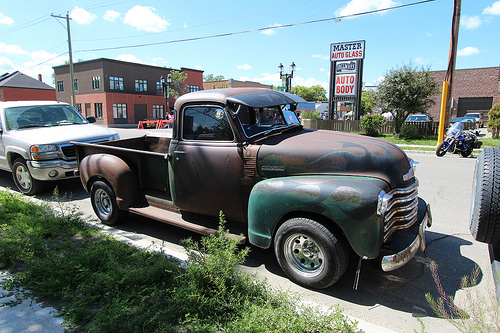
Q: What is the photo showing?
A: It is showing a road.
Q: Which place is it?
A: It is a road.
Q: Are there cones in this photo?
A: No, there are no cones.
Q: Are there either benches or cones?
A: No, there are no cones or benches.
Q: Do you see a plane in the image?
A: No, there are no airplanes.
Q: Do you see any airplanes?
A: No, there are no airplanes.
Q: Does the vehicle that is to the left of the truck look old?
A: Yes, the vehicle is old.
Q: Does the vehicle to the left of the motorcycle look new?
A: No, the vehicle is old.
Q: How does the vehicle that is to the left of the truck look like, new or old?
A: The vehicle is old.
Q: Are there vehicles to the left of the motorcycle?
A: Yes, there is a vehicle to the left of the motorcycle.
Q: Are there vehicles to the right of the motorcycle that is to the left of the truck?
A: No, the vehicle is to the left of the motorcycle.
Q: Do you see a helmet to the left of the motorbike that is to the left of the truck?
A: No, there is a vehicle to the left of the motorcycle.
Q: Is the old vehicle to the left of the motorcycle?
A: Yes, the vehicle is to the left of the motorcycle.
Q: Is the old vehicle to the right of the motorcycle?
A: No, the vehicle is to the left of the motorcycle.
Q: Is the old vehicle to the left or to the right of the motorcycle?
A: The vehicle is to the left of the motorcycle.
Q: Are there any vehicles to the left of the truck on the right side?
A: Yes, there is a vehicle to the left of the truck.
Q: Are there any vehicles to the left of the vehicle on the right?
A: Yes, there is a vehicle to the left of the truck.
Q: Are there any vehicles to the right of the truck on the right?
A: No, the vehicle is to the left of the truck.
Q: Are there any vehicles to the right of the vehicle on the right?
A: No, the vehicle is to the left of the truck.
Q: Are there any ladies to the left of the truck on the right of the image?
A: No, there is a vehicle to the left of the truck.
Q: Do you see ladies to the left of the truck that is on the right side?
A: No, there is a vehicle to the left of the truck.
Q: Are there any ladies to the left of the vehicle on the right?
A: No, there is a vehicle to the left of the truck.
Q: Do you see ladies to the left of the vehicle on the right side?
A: No, there is a vehicle to the left of the truck.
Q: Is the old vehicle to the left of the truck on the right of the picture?
A: Yes, the vehicle is to the left of the truck.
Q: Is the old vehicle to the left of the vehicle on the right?
A: Yes, the vehicle is to the left of the truck.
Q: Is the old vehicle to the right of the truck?
A: No, the vehicle is to the left of the truck.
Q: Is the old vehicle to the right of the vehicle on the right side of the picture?
A: No, the vehicle is to the left of the truck.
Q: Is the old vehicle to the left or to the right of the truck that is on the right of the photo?
A: The vehicle is to the left of the truck.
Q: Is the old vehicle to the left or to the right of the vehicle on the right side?
A: The vehicle is to the left of the truck.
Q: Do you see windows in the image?
A: Yes, there is a window.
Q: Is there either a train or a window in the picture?
A: Yes, there is a window.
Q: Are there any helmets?
A: No, there are no helmets.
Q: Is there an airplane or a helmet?
A: No, there are no helmets or airplanes.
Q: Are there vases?
A: No, there are no vases.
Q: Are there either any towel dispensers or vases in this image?
A: No, there are no vases or towel dispensers.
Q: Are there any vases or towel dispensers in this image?
A: No, there are no vases or towel dispensers.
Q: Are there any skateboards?
A: No, there are no skateboards.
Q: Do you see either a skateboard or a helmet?
A: No, there are no skateboards or helmets.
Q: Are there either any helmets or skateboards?
A: No, there are no skateboards or helmets.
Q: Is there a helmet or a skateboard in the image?
A: No, there are no skateboards or helmets.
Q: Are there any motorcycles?
A: Yes, there is a motorcycle.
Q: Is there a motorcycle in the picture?
A: Yes, there is a motorcycle.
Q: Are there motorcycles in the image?
A: Yes, there is a motorcycle.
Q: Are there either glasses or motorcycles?
A: Yes, there is a motorcycle.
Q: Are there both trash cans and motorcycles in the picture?
A: No, there is a motorcycle but no trash cans.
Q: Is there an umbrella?
A: No, there are no umbrellas.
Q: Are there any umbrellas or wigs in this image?
A: No, there are no umbrellas or wigs.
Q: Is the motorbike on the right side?
A: Yes, the motorbike is on the right of the image.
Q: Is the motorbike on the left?
A: No, the motorbike is on the right of the image.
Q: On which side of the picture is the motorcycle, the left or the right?
A: The motorcycle is on the right of the image.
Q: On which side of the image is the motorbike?
A: The motorbike is on the right of the image.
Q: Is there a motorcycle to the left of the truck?
A: Yes, there is a motorcycle to the left of the truck.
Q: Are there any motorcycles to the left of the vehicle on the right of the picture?
A: Yes, there is a motorcycle to the left of the truck.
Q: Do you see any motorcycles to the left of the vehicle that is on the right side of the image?
A: Yes, there is a motorcycle to the left of the truck.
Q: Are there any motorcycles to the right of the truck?
A: No, the motorcycle is to the left of the truck.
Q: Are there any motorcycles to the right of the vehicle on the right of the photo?
A: No, the motorcycle is to the left of the truck.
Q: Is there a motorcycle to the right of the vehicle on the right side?
A: No, the motorcycle is to the left of the truck.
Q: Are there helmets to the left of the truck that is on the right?
A: No, there is a motorcycle to the left of the truck.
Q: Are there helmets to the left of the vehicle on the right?
A: No, there is a motorcycle to the left of the truck.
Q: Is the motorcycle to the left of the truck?
A: Yes, the motorcycle is to the left of the truck.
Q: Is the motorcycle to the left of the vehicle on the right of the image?
A: Yes, the motorcycle is to the left of the truck.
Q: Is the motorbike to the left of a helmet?
A: No, the motorbike is to the left of the truck.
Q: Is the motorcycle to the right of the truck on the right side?
A: No, the motorcycle is to the left of the truck.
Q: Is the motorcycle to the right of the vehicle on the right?
A: No, the motorcycle is to the left of the truck.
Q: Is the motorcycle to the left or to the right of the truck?
A: The motorcycle is to the left of the truck.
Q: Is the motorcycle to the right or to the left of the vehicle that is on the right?
A: The motorcycle is to the left of the truck.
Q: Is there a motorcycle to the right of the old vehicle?
A: Yes, there is a motorcycle to the right of the vehicle.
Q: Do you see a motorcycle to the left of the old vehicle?
A: No, the motorcycle is to the right of the vehicle.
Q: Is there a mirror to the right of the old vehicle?
A: No, there is a motorcycle to the right of the vehicle.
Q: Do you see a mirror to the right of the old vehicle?
A: No, there is a motorcycle to the right of the vehicle.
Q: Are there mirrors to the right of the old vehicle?
A: No, there is a motorcycle to the right of the vehicle.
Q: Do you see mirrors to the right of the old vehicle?
A: No, there is a motorcycle to the right of the vehicle.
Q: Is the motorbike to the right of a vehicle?
A: Yes, the motorbike is to the right of a vehicle.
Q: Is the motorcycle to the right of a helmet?
A: No, the motorcycle is to the right of a vehicle.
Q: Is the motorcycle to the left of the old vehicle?
A: No, the motorcycle is to the right of the vehicle.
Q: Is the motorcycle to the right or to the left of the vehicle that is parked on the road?
A: The motorcycle is to the right of the vehicle.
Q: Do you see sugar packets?
A: No, there are no sugar packets.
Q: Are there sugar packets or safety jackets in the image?
A: No, there are no sugar packets or safety jackets.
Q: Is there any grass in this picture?
A: Yes, there is grass.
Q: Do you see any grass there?
A: Yes, there is grass.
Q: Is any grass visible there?
A: Yes, there is grass.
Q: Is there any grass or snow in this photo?
A: Yes, there is grass.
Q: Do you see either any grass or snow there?
A: Yes, there is grass.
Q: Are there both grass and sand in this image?
A: No, there is grass but no sand.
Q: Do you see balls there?
A: No, there are no balls.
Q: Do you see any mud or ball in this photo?
A: No, there are no balls or mud.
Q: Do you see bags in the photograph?
A: No, there are no bags.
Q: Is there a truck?
A: Yes, there is a truck.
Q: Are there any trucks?
A: Yes, there is a truck.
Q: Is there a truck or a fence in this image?
A: Yes, there is a truck.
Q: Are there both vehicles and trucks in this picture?
A: Yes, there are both a truck and a vehicle.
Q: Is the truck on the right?
A: Yes, the truck is on the right of the image.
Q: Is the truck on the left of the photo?
A: No, the truck is on the right of the image.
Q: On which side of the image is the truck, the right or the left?
A: The truck is on the right of the image.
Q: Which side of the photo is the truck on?
A: The truck is on the right of the image.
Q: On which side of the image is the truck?
A: The truck is on the right of the image.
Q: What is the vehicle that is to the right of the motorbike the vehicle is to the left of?
A: The vehicle is a truck.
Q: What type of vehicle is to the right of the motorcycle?
A: The vehicle is a truck.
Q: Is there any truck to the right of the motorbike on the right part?
A: Yes, there is a truck to the right of the motorcycle.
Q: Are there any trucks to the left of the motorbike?
A: No, the truck is to the right of the motorbike.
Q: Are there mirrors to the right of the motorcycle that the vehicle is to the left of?
A: No, there is a truck to the right of the motorbike.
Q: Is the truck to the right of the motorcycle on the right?
A: Yes, the truck is to the right of the motorcycle.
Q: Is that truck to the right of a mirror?
A: No, the truck is to the right of the motorcycle.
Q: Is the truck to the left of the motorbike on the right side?
A: No, the truck is to the right of the motorbike.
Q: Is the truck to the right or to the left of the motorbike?
A: The truck is to the right of the motorbike.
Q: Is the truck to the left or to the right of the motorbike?
A: The truck is to the right of the motorbike.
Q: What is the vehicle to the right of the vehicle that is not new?
A: The vehicle is a truck.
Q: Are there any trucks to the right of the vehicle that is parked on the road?
A: Yes, there is a truck to the right of the vehicle.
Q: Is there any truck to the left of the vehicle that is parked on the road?
A: No, the truck is to the right of the vehicle.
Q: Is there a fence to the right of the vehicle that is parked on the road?
A: No, there is a truck to the right of the vehicle.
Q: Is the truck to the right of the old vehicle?
A: Yes, the truck is to the right of the vehicle.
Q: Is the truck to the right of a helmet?
A: No, the truck is to the right of the vehicle.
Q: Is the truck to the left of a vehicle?
A: No, the truck is to the right of a vehicle.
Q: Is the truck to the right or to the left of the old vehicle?
A: The truck is to the right of the vehicle.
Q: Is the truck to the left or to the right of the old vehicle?
A: The truck is to the right of the vehicle.